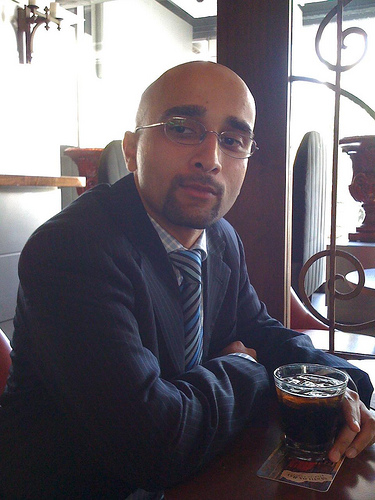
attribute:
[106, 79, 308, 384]
man — drinking, sitting, bald, dark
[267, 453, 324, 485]
coaster — colorful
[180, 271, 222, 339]
tie — blue, striped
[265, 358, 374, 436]
drink — cold, dark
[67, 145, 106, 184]
vase — red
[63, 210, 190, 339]
suit — dark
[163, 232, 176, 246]
shirt — blue